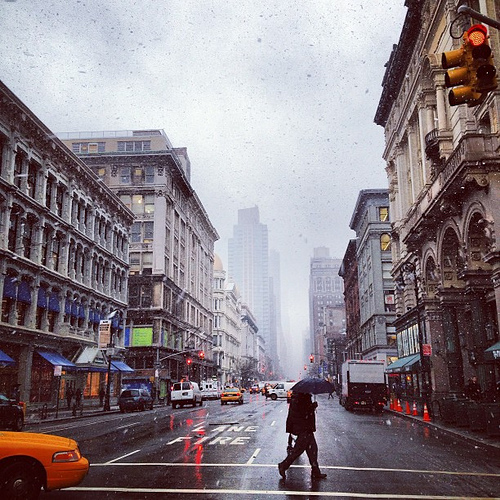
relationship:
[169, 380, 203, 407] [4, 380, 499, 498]
van driving on street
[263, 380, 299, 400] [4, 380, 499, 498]
van driving across street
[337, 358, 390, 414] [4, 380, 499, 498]
box truck parked on street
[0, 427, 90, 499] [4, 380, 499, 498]
taxi driving down street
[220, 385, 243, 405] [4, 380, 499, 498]
taxi driving down street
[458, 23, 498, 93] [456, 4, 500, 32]
stoplight hanging from pole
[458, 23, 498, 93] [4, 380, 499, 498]
stoplight hanging over street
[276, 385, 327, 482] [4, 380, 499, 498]
person crossing street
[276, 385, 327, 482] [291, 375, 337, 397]
person carrying umbrella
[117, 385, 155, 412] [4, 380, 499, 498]
car on street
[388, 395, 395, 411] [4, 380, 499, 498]
cone beside street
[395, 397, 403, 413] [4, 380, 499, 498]
cone beside street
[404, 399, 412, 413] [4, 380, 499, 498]
cone beside street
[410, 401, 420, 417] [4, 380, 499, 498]
cone beside street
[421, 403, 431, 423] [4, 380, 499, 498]
cone beside street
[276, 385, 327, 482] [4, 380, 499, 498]
person walking across street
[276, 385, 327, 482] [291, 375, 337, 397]
person holding umbrella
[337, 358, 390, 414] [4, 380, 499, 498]
box truck on street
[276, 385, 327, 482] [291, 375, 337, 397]
person with umbrella